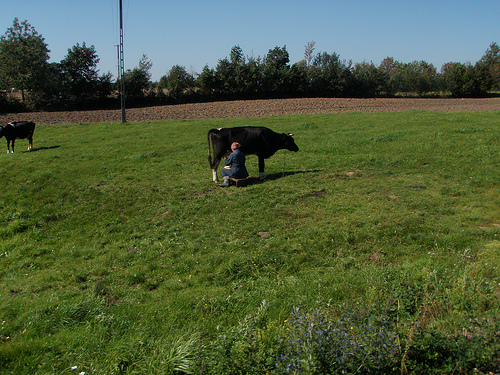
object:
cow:
[207, 126, 300, 182]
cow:
[0, 119, 37, 153]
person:
[218, 142, 249, 188]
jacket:
[225, 151, 249, 175]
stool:
[229, 176, 250, 186]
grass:
[4, 108, 500, 374]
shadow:
[239, 168, 321, 187]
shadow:
[22, 144, 60, 153]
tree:
[1, 17, 50, 105]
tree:
[62, 41, 100, 109]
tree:
[38, 60, 67, 112]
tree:
[97, 72, 117, 103]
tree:
[113, 54, 153, 103]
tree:
[157, 65, 193, 102]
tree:
[193, 65, 215, 95]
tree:
[216, 57, 236, 96]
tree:
[241, 62, 270, 98]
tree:
[261, 48, 291, 96]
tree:
[288, 58, 312, 98]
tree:
[310, 53, 349, 98]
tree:
[351, 61, 385, 99]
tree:
[377, 55, 408, 98]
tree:
[402, 58, 438, 97]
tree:
[433, 71, 446, 96]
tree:
[441, 61, 482, 99]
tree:
[474, 42, 500, 96]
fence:
[2, 89, 380, 102]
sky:
[0, 0, 498, 81]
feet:
[218, 182, 230, 187]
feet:
[11, 149, 14, 153]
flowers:
[278, 353, 296, 373]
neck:
[278, 133, 287, 149]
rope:
[282, 135, 287, 178]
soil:
[3, 94, 498, 113]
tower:
[119, 0, 128, 123]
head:
[282, 132, 299, 152]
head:
[0, 126, 4, 138]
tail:
[207, 127, 213, 168]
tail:
[30, 124, 36, 137]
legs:
[258, 156, 267, 181]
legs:
[212, 153, 220, 183]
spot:
[256, 229, 271, 240]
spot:
[346, 169, 354, 177]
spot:
[388, 194, 398, 202]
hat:
[231, 142, 242, 149]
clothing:
[221, 149, 247, 181]